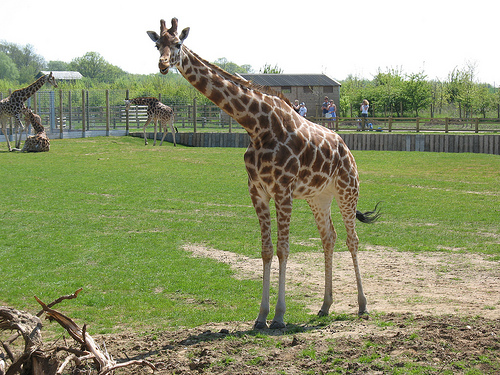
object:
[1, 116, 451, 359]
area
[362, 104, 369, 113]
shirt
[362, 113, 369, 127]
pants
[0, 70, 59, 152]
giraffes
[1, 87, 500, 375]
zoo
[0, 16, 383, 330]
exhibit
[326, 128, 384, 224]
rear end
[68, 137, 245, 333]
grassy field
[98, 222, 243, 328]
green field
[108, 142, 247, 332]
grassy field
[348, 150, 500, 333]
grassy field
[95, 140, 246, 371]
ground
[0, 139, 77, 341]
green field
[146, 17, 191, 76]
head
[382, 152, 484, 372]
ground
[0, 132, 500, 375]
field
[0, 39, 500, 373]
park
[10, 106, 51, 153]
giraffe crouching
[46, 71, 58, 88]
head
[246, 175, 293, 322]
front two legs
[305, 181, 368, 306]
back two legs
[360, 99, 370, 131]
person in a white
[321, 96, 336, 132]
two people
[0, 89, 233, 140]
wooden braches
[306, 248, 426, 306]
dry dead grass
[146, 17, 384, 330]
brown  white giraffe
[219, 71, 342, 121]
exhibit building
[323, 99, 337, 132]
woman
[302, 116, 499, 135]
exhibit fence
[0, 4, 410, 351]
giraffe exhibit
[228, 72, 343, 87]
building roof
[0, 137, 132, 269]
grassy field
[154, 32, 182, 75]
face of a giraffe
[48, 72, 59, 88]
face of a giraffe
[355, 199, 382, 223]
tail of a giraffe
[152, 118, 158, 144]
leg of a giraffe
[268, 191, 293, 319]
leg of a giraffe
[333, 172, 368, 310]
leg of a giraffe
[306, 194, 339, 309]
leg of a giraffe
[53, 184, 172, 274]
giraffe in a grassy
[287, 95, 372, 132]
people looking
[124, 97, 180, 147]
giraffe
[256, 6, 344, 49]
white clouds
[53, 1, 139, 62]
louds in blue sky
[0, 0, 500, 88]
blue sky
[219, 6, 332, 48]
white clouds in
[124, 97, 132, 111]
head of the giraffe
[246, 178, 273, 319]
legs of the giraffe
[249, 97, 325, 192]
brown and white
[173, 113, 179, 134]
"tail of the giraffe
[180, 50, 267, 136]
neck of the giraffe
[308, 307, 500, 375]
brown dirt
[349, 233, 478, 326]
grass on the ground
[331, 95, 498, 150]
fence in distance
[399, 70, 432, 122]
trees in  distance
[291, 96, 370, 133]
people in distance